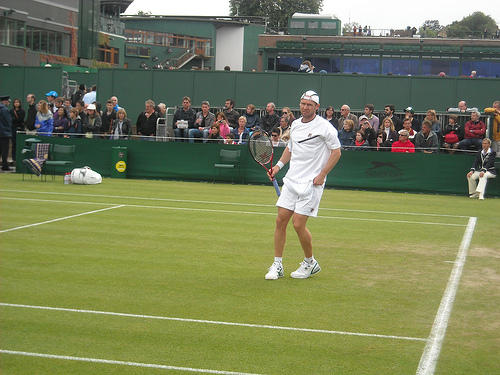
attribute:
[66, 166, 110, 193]
duffel bag — white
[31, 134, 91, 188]
chair — green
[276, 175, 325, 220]
shorts — white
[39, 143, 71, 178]
chair — green 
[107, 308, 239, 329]
line — white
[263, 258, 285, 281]
shoe — white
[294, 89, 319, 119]
head — player's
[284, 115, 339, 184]
shirt — white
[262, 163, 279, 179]
hand — man's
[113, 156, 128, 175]
dot — yellow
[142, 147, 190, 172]
fence — green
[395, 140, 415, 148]
jacket — red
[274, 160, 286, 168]
wristband — white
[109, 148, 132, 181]
trash can — green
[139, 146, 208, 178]
banner — green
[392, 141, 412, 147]
sweater — red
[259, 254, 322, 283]
tennis shoes — white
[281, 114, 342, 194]
t-shirt — white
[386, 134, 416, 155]
sweatshirt — red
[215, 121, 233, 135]
sweatshirt — pink